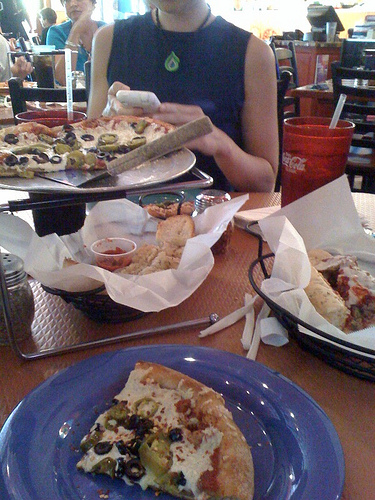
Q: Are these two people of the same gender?
A: Yes, all the people are female.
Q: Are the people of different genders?
A: No, all the people are female.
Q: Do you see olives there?
A: Yes, there are olives.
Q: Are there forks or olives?
A: Yes, there are olives.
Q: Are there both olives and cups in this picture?
A: Yes, there are both olives and a cup.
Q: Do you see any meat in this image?
A: No, there is no meat.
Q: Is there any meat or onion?
A: No, there are no meat or onions.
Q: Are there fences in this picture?
A: No, there are no fences.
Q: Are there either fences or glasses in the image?
A: No, there are no fences or glasses.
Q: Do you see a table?
A: Yes, there is a table.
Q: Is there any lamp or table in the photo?
A: Yes, there is a table.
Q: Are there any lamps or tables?
A: Yes, there is a table.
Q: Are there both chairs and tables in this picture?
A: Yes, there are both a table and a chair.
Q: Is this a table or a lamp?
A: This is a table.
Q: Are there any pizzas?
A: Yes, there is a pizza.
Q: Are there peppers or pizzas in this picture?
A: Yes, there is a pizza.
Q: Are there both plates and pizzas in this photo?
A: Yes, there are both a pizza and a plate.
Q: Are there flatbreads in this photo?
A: No, there are no flatbreads.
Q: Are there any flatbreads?
A: No, there are no flatbreads.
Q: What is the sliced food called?
A: The food is a pizza.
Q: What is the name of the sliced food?
A: The food is a pizza.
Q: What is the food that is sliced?
A: The food is a pizza.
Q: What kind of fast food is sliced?
A: The fast food is a pizza.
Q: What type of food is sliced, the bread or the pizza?
A: The pizza is sliced.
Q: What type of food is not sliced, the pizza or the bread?
A: The bread is not sliced.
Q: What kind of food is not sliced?
A: The food is a bread.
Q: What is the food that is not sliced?
A: The food is a bread.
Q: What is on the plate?
A: The pizza is on the plate.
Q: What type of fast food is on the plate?
A: The food is a pizza.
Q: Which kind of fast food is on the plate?
A: The food is a pizza.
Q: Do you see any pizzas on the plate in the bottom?
A: Yes, there is a pizza on the plate.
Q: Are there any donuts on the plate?
A: No, there is a pizza on the plate.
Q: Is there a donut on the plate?
A: No, there is a pizza on the plate.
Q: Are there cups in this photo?
A: Yes, there is a cup.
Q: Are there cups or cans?
A: Yes, there is a cup.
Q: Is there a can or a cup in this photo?
A: Yes, there is a cup.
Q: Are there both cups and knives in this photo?
A: No, there is a cup but no knives.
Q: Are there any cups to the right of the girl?
A: Yes, there is a cup to the right of the girl.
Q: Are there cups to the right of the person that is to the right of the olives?
A: Yes, there is a cup to the right of the girl.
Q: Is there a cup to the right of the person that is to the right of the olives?
A: Yes, there is a cup to the right of the girl.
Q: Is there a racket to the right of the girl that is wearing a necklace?
A: No, there is a cup to the right of the girl.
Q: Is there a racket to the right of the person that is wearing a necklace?
A: No, there is a cup to the right of the girl.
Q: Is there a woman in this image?
A: Yes, there is a woman.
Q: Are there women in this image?
A: Yes, there is a woman.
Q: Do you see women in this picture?
A: Yes, there is a woman.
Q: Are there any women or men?
A: Yes, there is a woman.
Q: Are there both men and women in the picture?
A: No, there is a woman but no men.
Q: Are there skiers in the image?
A: No, there are no skiers.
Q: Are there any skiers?
A: No, there are no skiers.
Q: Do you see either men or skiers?
A: No, there are no skiers or men.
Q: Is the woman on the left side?
A: Yes, the woman is on the left of the image.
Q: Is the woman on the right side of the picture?
A: No, the woman is on the left of the image.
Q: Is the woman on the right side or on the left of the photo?
A: The woman is on the left of the image.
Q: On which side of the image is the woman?
A: The woman is on the left of the image.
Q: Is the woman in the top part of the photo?
A: Yes, the woman is in the top of the image.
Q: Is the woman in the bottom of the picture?
A: No, the woman is in the top of the image.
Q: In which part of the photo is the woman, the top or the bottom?
A: The woman is in the top of the image.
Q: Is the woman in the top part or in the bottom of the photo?
A: The woman is in the top of the image.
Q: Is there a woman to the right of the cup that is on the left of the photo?
A: Yes, there is a woman to the right of the cup.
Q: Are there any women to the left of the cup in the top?
A: No, the woman is to the right of the cup.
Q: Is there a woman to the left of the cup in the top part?
A: No, the woman is to the right of the cup.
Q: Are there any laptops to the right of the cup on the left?
A: No, there is a woman to the right of the cup.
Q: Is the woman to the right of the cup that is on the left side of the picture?
A: Yes, the woman is to the right of the cup.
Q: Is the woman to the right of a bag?
A: No, the woman is to the right of the cup.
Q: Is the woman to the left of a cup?
A: No, the woman is to the right of a cup.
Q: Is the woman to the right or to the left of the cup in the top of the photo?
A: The woman is to the right of the cup.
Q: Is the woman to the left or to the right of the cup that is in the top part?
A: The woman is to the right of the cup.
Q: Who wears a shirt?
A: The woman wears a shirt.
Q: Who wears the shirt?
A: The woman wears a shirt.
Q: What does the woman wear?
A: The woman wears a shirt.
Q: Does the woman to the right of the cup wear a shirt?
A: Yes, the woman wears a shirt.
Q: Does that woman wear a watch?
A: No, the woman wears a shirt.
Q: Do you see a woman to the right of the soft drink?
A: Yes, there is a woman to the right of the soft drink.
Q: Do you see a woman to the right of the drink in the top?
A: Yes, there is a woman to the right of the soft drink.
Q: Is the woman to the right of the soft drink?
A: Yes, the woman is to the right of the soft drink.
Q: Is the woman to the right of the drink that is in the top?
A: Yes, the woman is to the right of the soft drink.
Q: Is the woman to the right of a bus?
A: No, the woman is to the right of the soft drink.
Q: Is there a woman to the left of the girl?
A: Yes, there is a woman to the left of the girl.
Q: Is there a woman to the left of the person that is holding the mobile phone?
A: Yes, there is a woman to the left of the girl.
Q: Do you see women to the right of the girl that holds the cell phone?
A: No, the woman is to the left of the girl.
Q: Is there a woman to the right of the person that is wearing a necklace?
A: No, the woman is to the left of the girl.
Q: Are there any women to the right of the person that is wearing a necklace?
A: No, the woman is to the left of the girl.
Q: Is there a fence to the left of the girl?
A: No, there is a woman to the left of the girl.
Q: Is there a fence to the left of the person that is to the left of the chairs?
A: No, there is a woman to the left of the girl.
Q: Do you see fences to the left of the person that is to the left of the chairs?
A: No, there is a woman to the left of the girl.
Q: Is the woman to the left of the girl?
A: Yes, the woman is to the left of the girl.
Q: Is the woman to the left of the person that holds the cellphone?
A: Yes, the woman is to the left of the girl.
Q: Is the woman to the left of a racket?
A: No, the woman is to the left of the girl.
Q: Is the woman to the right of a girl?
A: No, the woman is to the left of a girl.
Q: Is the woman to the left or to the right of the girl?
A: The woman is to the left of the girl.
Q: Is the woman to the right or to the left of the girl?
A: The woman is to the left of the girl.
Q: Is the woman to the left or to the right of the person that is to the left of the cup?
A: The woman is to the left of the girl.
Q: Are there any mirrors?
A: No, there are no mirrors.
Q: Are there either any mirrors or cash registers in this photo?
A: No, there are no mirrors or cash registers.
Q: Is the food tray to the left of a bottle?
A: No, the food tray is to the left of a cup.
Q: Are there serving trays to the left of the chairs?
A: Yes, there is a serving tray to the left of the chairs.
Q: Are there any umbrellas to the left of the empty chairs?
A: No, there is a serving tray to the left of the chairs.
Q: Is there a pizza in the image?
A: Yes, there is a pizza.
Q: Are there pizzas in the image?
A: Yes, there is a pizza.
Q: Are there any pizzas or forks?
A: Yes, there is a pizza.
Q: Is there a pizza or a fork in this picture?
A: Yes, there is a pizza.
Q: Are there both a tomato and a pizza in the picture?
A: No, there is a pizza but no tomatoes.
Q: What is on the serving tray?
A: The pizza is on the food tray.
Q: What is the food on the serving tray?
A: The food is a pizza.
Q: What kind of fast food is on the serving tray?
A: The food is a pizza.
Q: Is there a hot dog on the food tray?
A: No, there is a pizza on the food tray.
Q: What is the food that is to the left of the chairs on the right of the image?
A: The food is a pizza.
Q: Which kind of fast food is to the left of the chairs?
A: The food is a pizza.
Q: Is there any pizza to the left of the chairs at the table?
A: Yes, there is a pizza to the left of the chairs.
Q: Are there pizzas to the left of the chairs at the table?
A: Yes, there is a pizza to the left of the chairs.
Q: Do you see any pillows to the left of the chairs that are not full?
A: No, there is a pizza to the left of the chairs.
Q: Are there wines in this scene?
A: No, there are no wines.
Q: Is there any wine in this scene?
A: No, there are no wines.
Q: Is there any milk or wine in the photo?
A: No, there are no wines or milk.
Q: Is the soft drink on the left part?
A: Yes, the soft drink is on the left of the image.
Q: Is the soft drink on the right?
A: No, the soft drink is on the left of the image.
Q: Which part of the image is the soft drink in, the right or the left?
A: The soft drink is on the left of the image.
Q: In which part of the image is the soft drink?
A: The soft drink is on the left of the image.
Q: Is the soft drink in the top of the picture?
A: Yes, the soft drink is in the top of the image.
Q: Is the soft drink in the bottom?
A: No, the soft drink is in the top of the image.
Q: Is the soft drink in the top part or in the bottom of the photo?
A: The soft drink is in the top of the image.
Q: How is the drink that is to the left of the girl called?
A: The drink is a soft drink.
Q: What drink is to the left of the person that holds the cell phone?
A: The drink is a soft drink.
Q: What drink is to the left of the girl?
A: The drink is a soft drink.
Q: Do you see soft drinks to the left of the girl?
A: Yes, there is a soft drink to the left of the girl.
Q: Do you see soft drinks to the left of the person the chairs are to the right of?
A: Yes, there is a soft drink to the left of the girl.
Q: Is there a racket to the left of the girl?
A: No, there is a soft drink to the left of the girl.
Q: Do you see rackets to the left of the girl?
A: No, there is a soft drink to the left of the girl.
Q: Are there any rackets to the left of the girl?
A: No, there is a soft drink to the left of the girl.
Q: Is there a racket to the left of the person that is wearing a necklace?
A: No, there is a soft drink to the left of the girl.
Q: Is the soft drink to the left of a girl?
A: Yes, the soft drink is to the left of a girl.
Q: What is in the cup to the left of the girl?
A: The soft drink is in the cup.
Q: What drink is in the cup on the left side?
A: The drink is a soft drink.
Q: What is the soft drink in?
A: The soft drink is in the cup.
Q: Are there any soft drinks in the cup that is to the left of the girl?
A: Yes, there is a soft drink in the cup.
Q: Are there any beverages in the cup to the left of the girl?
A: No, there is a soft drink in the cup.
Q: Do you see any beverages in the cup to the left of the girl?
A: No, there is a soft drink in the cup.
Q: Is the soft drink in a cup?
A: Yes, the soft drink is in a cup.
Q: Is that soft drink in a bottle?
A: No, the soft drink is in a cup.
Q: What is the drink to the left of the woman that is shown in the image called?
A: The drink is a soft drink.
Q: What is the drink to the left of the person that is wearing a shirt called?
A: The drink is a soft drink.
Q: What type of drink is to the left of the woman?
A: The drink is a soft drink.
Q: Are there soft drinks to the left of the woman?
A: Yes, there is a soft drink to the left of the woman.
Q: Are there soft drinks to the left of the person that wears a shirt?
A: Yes, there is a soft drink to the left of the woman.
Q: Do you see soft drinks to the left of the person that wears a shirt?
A: Yes, there is a soft drink to the left of the woman.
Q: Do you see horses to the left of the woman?
A: No, there is a soft drink to the left of the woman.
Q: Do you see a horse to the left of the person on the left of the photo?
A: No, there is a soft drink to the left of the woman.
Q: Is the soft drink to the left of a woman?
A: Yes, the soft drink is to the left of a woman.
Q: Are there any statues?
A: No, there are no statues.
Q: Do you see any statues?
A: No, there are no statues.